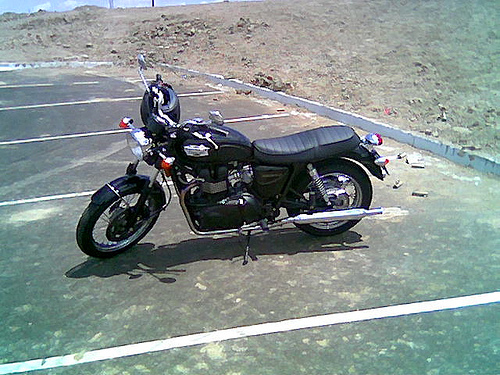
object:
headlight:
[125, 128, 151, 161]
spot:
[0, 136, 499, 374]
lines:
[0, 63, 499, 375]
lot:
[0, 54, 496, 371]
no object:
[122, 231, 419, 327]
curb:
[151, 52, 500, 213]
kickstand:
[242, 230, 257, 265]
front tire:
[75, 183, 162, 258]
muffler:
[282, 207, 382, 223]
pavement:
[1, 60, 500, 375]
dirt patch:
[0, 0, 499, 150]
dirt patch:
[386, 36, 499, 123]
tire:
[286, 157, 372, 237]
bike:
[75, 55, 390, 259]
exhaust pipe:
[281, 206, 382, 224]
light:
[364, 132, 383, 146]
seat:
[251, 125, 360, 165]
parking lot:
[0, 54, 499, 375]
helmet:
[139, 80, 181, 125]